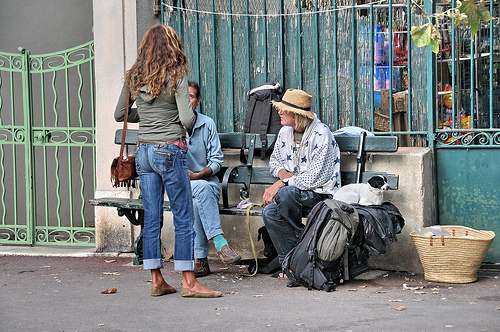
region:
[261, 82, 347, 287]
person in a straw hat sitting on a bench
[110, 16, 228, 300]
woman in green hoody facing the bench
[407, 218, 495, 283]
large woven basket sitting on the ground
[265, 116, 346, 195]
long sleeved shirt with blue stars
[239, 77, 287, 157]
black backpack behind the bench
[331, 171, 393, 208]
small black and white dog sitting on the bench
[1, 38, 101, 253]
green painted metal gate to the left of the bench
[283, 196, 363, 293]
large black and tan backpack sitting on the ground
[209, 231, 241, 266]
a brown loafer with a green sock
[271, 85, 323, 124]
a ragged straw hat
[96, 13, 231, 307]
woman with long brown hair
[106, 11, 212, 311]
woman wearing gray hoodie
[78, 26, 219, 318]
woman wearing a suede purse on her shoulder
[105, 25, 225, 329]
woman wearing blue jeans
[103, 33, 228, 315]
woman wearing a pair of flats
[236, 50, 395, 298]
woman wearing straw hat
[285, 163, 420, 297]
dog laying on a stack of clothing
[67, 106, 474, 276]
people sitting on wooden bench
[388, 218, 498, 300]
large straw bag sitting by a bench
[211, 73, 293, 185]
large black back pack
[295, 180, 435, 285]
Bags by a bench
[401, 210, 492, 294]
Basket on a sidewalk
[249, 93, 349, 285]
Person sitting on a bench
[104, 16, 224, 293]
Woman standing by a bench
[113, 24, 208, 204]
Woman with long hair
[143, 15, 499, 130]
Teal colored railing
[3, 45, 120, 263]
Green colored fence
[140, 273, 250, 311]
Flat shoes on a woman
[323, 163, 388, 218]
Dog sitting on a bench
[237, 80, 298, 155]
Bag sitting on a wall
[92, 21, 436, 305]
three people talking to one another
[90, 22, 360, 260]
two people sitting on bench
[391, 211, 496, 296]
one wicker basket in photo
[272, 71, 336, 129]
woman wearing hat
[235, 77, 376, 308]
suitcases next to woman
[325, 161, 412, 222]
white and black animal in photo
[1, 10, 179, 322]
green fence near bench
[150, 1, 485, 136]
fence behind people talking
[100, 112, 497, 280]
concrete behind bench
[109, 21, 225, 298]
The woman her back turned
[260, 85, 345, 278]
The person in the straw hat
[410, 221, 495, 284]
The tan bag on the ground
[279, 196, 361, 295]
The black backpack on the ground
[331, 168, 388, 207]
The dog on the bench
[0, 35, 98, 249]
The bright green fence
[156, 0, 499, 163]
The dark green fence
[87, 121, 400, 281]
The bench the people are sitting on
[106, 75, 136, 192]
The brown bag of the woman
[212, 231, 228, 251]
The person's green sock